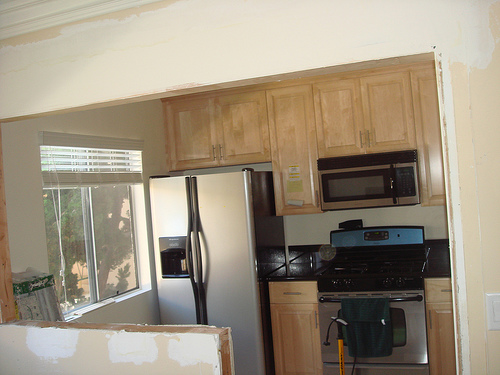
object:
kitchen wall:
[0, 319, 237, 375]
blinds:
[38, 130, 148, 184]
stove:
[317, 255, 429, 293]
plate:
[481, 292, 499, 335]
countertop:
[267, 250, 318, 282]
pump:
[323, 314, 349, 375]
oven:
[313, 287, 429, 366]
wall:
[0, 325, 233, 375]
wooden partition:
[0, 314, 239, 375]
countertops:
[425, 239, 451, 278]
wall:
[434, 0, 500, 375]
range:
[315, 248, 436, 280]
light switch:
[483, 292, 500, 331]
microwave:
[314, 148, 423, 211]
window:
[41, 182, 151, 321]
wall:
[3, 121, 47, 270]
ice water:
[158, 236, 191, 277]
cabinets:
[266, 278, 325, 375]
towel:
[340, 296, 397, 360]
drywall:
[0, 318, 237, 375]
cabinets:
[158, 93, 419, 215]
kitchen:
[0, 51, 463, 375]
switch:
[483, 292, 500, 331]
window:
[36, 131, 152, 323]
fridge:
[147, 170, 274, 374]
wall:
[0, 100, 176, 328]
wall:
[0, 0, 497, 375]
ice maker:
[156, 234, 191, 279]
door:
[145, 174, 191, 323]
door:
[190, 169, 267, 374]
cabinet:
[160, 88, 219, 174]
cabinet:
[214, 79, 273, 169]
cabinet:
[266, 82, 323, 218]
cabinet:
[310, 70, 367, 160]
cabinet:
[355, 65, 416, 154]